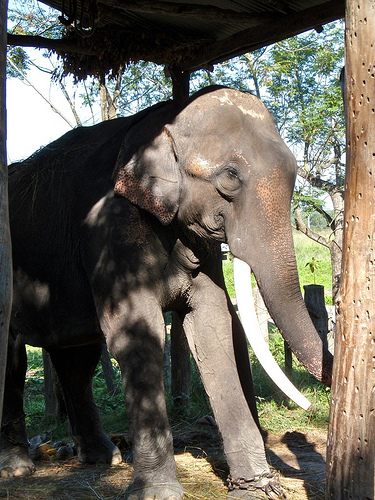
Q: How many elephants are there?
A: One.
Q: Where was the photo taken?
A: At a elephant sanctuary.